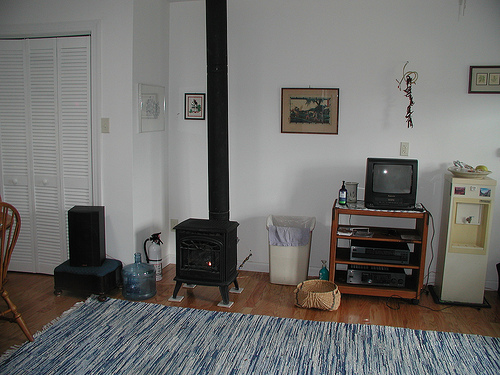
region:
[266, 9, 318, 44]
this is the wall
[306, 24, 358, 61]
the wall is white in color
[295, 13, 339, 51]
the wall is clean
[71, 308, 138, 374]
this is a carpet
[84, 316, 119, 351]
the carpet is blue in color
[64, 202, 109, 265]
this is a speaker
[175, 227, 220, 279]
this is a stove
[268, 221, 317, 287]
this is a bin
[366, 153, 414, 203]
this is a TV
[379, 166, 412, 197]
the screen is off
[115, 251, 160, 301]
Blue water bottle on floor.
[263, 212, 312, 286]
White trash can on floor.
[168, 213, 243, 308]
Black cast iron heater.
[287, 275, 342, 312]
Wicker basket on floor.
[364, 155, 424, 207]
Small black television on stand.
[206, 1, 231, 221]
Long black metal pipe heater.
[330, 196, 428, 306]
Brown wooden stand with three shelves.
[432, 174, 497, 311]
White and beige water cooler.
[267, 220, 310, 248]
White towel folded over trash can.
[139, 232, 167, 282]
White and black fire hydrant.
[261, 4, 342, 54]
this is the wall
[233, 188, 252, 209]
the wall is white in color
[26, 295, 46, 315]
this is the floor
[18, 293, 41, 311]
the floor is brown in color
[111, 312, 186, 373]
this is a carpet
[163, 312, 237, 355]
the carpet is blue in color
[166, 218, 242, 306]
this is an oven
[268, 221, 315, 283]
this is a dust bin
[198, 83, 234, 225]
the chimney is black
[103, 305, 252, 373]
the carpet is blue in color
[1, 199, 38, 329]
the chair is brown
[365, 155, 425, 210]
tv is on the stool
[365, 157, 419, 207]
the tv is off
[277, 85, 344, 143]
picture is on the wall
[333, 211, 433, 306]
the cabinet has four shelves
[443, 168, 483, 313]
the water cooler is white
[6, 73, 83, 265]
the closet s white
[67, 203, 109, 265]
the speaker is black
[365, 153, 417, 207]
The t.v. on the stand.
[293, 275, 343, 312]
The whicker basket on the floor.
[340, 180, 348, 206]
The black bottle next to the t.v.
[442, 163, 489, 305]
The water machine to the right of the t.v.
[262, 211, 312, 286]
The white trash can.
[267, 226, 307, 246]
The wash cloth hanging on the trash can.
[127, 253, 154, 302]
The water gallon on the floor.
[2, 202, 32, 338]
The wooden chair on the left.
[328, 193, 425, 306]
The stand the t.v. is on.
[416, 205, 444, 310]
The wires next to the wooden stand.